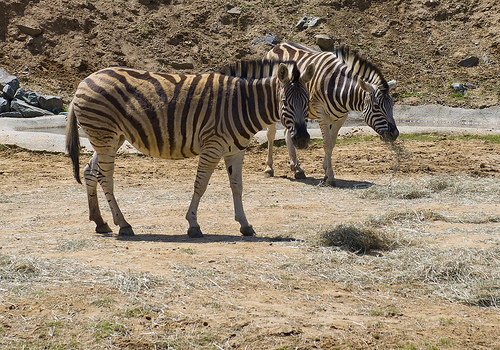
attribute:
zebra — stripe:
[53, 52, 305, 252]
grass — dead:
[364, 212, 463, 341]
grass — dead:
[372, 189, 480, 316]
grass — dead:
[348, 234, 425, 348]